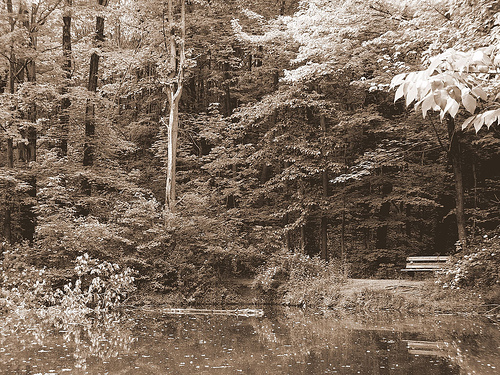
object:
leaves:
[0, 327, 12, 336]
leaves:
[100, 228, 115, 240]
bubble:
[196, 337, 209, 345]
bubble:
[386, 338, 396, 344]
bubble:
[378, 365, 387, 370]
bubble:
[139, 353, 151, 360]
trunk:
[77, 0, 110, 218]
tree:
[95, 0, 245, 215]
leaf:
[115, 216, 127, 223]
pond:
[0, 298, 499, 374]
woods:
[0, 0, 497, 320]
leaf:
[333, 176, 345, 184]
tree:
[0, 250, 136, 334]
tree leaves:
[385, 70, 407, 95]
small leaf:
[326, 160, 340, 173]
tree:
[228, 0, 499, 256]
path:
[226, 276, 423, 288]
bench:
[398, 255, 452, 281]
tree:
[50, 1, 78, 209]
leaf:
[198, 212, 209, 221]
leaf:
[145, 231, 155, 240]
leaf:
[157, 63, 170, 76]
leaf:
[252, 206, 268, 216]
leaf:
[277, 85, 286, 95]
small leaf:
[418, 93, 435, 120]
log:
[159, 307, 261, 317]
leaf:
[196, 213, 214, 227]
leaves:
[458, 92, 477, 116]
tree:
[75, 0, 113, 219]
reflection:
[398, 337, 456, 360]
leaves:
[470, 86, 487, 103]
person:
[218, 281, 229, 306]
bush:
[0, 250, 138, 322]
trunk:
[160, 27, 180, 207]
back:
[401, 253, 451, 268]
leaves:
[322, 43, 340, 52]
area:
[318, 272, 447, 312]